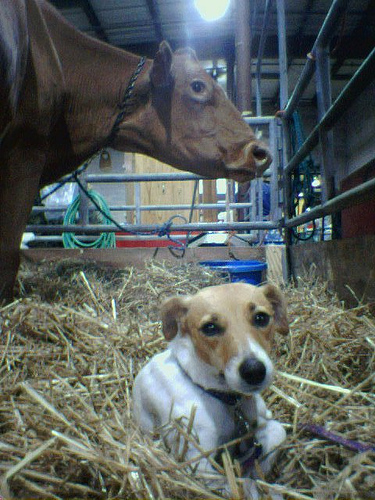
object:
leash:
[221, 400, 262, 472]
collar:
[173, 354, 247, 408]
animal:
[131, 278, 290, 497]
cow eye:
[186, 78, 210, 93]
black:
[194, 84, 202, 91]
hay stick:
[277, 367, 366, 397]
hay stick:
[17, 373, 74, 428]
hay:
[0, 256, 375, 499]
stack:
[0, 261, 375, 498]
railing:
[22, 167, 282, 253]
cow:
[0, 0, 276, 306]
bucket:
[194, 260, 267, 286]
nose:
[240, 355, 266, 384]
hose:
[60, 188, 118, 256]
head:
[157, 280, 291, 390]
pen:
[0, 1, 375, 499]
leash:
[296, 421, 375, 457]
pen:
[21, 242, 291, 290]